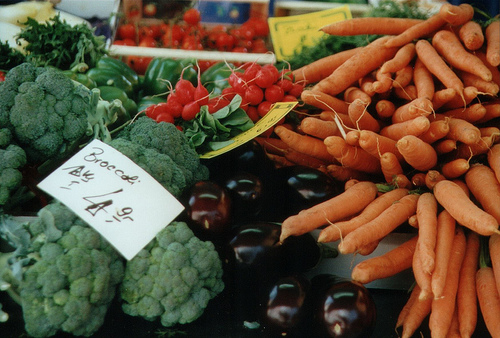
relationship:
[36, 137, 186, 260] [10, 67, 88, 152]
paper on broccoli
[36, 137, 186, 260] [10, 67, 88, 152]
paper on top of broccoli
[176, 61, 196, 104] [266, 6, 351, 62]
radish by sign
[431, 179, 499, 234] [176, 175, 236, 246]
carrot by eggplant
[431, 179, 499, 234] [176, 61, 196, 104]
carrot by radish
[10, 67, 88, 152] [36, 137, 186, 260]
broccoli under paper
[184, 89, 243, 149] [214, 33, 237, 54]
kale behind pepper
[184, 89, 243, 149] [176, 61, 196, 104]
kale by radish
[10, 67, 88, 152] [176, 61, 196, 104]
broccoli by radish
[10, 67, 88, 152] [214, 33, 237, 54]
broccoli by pepper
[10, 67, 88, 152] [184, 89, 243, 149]
broccoli by kale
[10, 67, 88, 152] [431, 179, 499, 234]
broccoli by carrot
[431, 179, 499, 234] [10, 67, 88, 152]
carrot by broccoli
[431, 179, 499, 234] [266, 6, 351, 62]
carrot by sign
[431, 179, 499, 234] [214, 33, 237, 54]
carrot by pepper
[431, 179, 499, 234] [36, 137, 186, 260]
carrot by paper